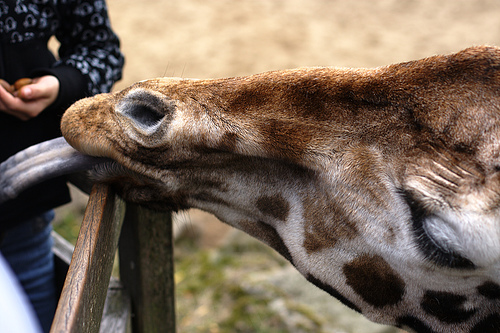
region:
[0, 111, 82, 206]
giraffe's tongue is black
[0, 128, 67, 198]
giraffe's tongue is black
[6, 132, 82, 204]
giraffe's tongue is black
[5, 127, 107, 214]
giraffe's tongue is black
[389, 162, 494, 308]
giraffe's eye is closed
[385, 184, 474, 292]
giraffe's eye is closed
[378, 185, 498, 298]
giraffe's eye is closed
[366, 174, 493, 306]
giraffe's eye is closed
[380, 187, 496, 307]
giraffe's eye is closed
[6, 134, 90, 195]
long gray tongue of giraffe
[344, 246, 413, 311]
large brown spot on giraffe face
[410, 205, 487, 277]
closed eye and long black lashes of giraffe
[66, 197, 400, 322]
patch of green grass under giraffe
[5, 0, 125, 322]
woman feeding giraffe in zoo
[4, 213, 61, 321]
woman wearing blue jeans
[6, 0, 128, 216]
woman wears old blue on blue floral sweater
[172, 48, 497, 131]
brown fur forehead of giraffe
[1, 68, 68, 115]
woman's hand with food for giraffe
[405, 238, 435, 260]
part of an eyelid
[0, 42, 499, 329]
giraffe with his tongue sticking out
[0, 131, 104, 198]
black tongue of the giraffe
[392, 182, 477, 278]
giraffes closed eye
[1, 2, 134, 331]
person standing just beyond the giraffe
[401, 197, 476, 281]
giraffes eye lashes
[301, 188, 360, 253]
big brown spot on the giraffe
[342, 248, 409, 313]
big brown spot on the giraffe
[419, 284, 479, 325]
big brown spot on the giraffe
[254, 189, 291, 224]
big brown spot on the giraffe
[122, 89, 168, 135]
open nostril of a giraffe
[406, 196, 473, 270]
closed eye of a giraffe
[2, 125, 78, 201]
long tongue of a giraffe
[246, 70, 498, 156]
brown fur on a giraffe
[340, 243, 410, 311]
brown spot on a giraffe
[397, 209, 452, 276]
long eyelashes on a giraffe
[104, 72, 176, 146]
nose of a giraffe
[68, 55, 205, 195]
nose of the giraffe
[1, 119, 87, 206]
tongue of the giraffe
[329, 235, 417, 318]
brown spot on the animal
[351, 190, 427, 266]
white fur on the giraffe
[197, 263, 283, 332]
grass on the ground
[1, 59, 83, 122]
hand of a person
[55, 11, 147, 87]
arm of the person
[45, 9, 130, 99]
black and white sleeve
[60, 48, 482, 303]
mouth of a giraffe on the wood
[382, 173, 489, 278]
eyeball of the giraffe which is closed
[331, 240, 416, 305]
brown spot on the face of the giraffe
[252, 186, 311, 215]
brown spot on the face of the giraffe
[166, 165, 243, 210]
brown spot on the face of the giraffe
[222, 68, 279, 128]
brown spot on the face of the giraffe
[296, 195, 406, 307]
Spots on a giraffe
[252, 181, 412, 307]
Spots on a giraffe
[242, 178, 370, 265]
Spots on a giraffe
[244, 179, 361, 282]
Spots on a giraffe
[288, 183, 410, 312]
Spots on a giraffe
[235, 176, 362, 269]
Spots on a giraffe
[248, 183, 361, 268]
Spots on a giraffe